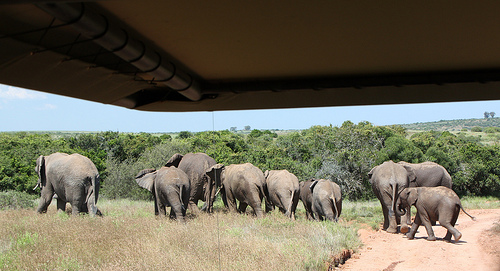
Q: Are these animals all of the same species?
A: Yes, all the animals are elephants.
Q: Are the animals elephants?
A: Yes, all the animals are elephants.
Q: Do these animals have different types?
A: No, all the animals are elephants.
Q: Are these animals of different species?
A: No, all the animals are elephants.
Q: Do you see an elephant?
A: Yes, there is an elephant.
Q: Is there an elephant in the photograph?
A: Yes, there is an elephant.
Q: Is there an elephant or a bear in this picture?
A: Yes, there is an elephant.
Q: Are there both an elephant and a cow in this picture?
A: No, there is an elephant but no cows.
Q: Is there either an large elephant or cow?
A: Yes, there is a large elephant.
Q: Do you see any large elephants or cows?
A: Yes, there is a large elephant.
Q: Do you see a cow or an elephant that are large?
A: Yes, the elephant is large.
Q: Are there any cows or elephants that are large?
A: Yes, the elephant is large.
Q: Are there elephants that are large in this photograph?
A: Yes, there is a large elephant.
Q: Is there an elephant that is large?
A: Yes, there is an elephant that is large.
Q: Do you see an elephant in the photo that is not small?
A: Yes, there is a large elephant.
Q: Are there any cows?
A: No, there are no cows.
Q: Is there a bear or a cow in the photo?
A: No, there are no cows or bears.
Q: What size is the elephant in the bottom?
A: The elephant is large.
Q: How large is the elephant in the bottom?
A: The elephant is large.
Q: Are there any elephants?
A: Yes, there is an elephant.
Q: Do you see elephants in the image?
A: Yes, there is an elephant.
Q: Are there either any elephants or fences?
A: Yes, there is an elephant.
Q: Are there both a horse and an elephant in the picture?
A: No, there is an elephant but no horses.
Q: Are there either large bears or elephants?
A: Yes, there is a large elephant.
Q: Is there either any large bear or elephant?
A: Yes, there is a large elephant.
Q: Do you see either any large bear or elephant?
A: Yes, there is a large elephant.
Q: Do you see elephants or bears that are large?
A: Yes, the elephant is large.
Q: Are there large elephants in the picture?
A: Yes, there is a large elephant.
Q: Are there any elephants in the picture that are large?
A: Yes, there is a large elephant.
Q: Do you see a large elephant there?
A: Yes, there is a large elephant.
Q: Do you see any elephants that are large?
A: Yes, there is an elephant that is large.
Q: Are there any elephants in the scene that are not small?
A: Yes, there is a large elephant.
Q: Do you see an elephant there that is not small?
A: Yes, there is a large elephant.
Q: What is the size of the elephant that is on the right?
A: The elephant is large.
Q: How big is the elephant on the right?
A: The elephant is large.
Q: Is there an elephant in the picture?
A: Yes, there is an elephant.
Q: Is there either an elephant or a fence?
A: Yes, there is an elephant.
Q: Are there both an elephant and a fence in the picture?
A: No, there is an elephant but no fences.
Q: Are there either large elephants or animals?
A: Yes, there is a large elephant.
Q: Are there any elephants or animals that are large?
A: Yes, the elephant is large.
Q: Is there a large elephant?
A: Yes, there is a large elephant.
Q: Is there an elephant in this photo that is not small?
A: Yes, there is a large elephant.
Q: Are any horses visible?
A: No, there are no horses.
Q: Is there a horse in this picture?
A: No, there are no horses.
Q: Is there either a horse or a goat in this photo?
A: No, there are no horses or goats.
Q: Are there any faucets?
A: No, there are no faucets.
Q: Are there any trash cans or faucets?
A: No, there are no faucets or trash cans.